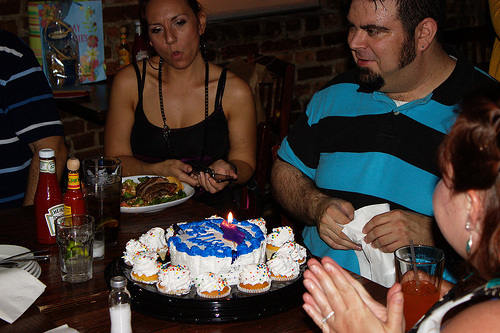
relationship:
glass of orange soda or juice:
[391, 241, 446, 331] [56, 197, 96, 310]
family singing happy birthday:
[2, 71, 496, 333] [128, 173, 345, 333]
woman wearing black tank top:
[104, 2, 253, 200] [119, 69, 245, 154]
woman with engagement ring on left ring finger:
[295, 258, 362, 333] [308, 277, 356, 333]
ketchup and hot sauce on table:
[39, 162, 61, 280] [53, 287, 97, 313]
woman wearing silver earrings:
[300, 91, 497, 331] [463, 219, 475, 259]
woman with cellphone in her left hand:
[120, 59, 255, 109] [206, 143, 235, 283]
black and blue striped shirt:
[300, 88, 494, 209] [276, 75, 464, 298]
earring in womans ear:
[461, 217, 485, 260] [461, 191, 481, 231]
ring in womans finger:
[323, 306, 340, 327] [298, 271, 337, 322]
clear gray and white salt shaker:
[94, 279, 136, 333] [95, 276, 160, 331]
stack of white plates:
[17, 236, 48, 333] [0, 245, 45, 287]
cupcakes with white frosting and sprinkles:
[120, 210, 317, 298] [140, 211, 290, 313]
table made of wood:
[186, 274, 290, 331] [174, 317, 269, 333]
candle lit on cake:
[220, 210, 243, 243] [166, 215, 268, 274]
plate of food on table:
[117, 164, 178, 208] [20, 131, 341, 330]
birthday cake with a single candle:
[173, 206, 264, 276] [219, 203, 250, 311]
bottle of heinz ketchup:
[31, 146, 66, 247] [38, 162, 77, 261]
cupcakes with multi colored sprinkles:
[124, 207, 244, 311] [159, 264, 189, 279]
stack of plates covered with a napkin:
[3, 243, 40, 333] [1, 266, 44, 333]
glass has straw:
[391, 241, 446, 331] [403, 235, 422, 275]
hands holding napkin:
[305, 187, 427, 277] [339, 202, 384, 244]